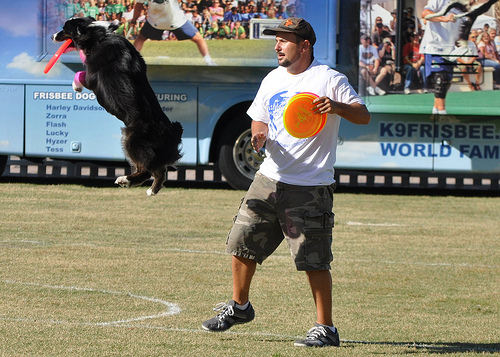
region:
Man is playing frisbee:
[194, 12, 369, 355]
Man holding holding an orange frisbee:
[198, 8, 379, 349]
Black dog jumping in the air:
[31, 11, 201, 208]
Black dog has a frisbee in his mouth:
[33, 10, 195, 215]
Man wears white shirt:
[198, 11, 366, 353]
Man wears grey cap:
[183, 7, 379, 353]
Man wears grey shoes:
[196, 10, 375, 355]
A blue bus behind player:
[7, 5, 499, 177]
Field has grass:
[3, 172, 498, 353]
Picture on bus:
[347, 1, 499, 116]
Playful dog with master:
[35, 10, 436, 350]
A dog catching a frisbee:
[13, 1, 215, 278]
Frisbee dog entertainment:
[19, 2, 405, 349]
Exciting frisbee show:
[8, 5, 498, 353]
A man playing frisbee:
[188, 9, 409, 347]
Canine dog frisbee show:
[17, 8, 451, 346]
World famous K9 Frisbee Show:
[6, 6, 498, 249]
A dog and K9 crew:
[15, 7, 412, 343]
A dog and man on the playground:
[23, 5, 497, 345]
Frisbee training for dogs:
[19, 7, 403, 347]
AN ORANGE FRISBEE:
[274, 88, 336, 141]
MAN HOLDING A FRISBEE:
[201, 13, 368, 353]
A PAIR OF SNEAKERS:
[196, 296, 350, 351]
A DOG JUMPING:
[34, 11, 199, 198]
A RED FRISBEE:
[41, 33, 78, 78]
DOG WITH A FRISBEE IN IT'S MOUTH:
[34, 12, 207, 203]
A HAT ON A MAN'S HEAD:
[259, 15, 336, 75]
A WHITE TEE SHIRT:
[224, 63, 364, 191]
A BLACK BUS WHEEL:
[206, 103, 306, 195]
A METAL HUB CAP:
[227, 113, 287, 183]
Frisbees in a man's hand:
[284, 87, 335, 141]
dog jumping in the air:
[46, 17, 183, 198]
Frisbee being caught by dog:
[37, 15, 77, 73]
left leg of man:
[281, 177, 341, 347]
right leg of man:
[201, 167, 281, 327]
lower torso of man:
[202, 162, 345, 349]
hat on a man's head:
[260, 16, 318, 43]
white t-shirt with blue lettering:
[236, 56, 371, 182]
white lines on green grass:
[11, 217, 498, 354]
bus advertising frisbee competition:
[2, 1, 498, 186]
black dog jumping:
[56, 17, 186, 194]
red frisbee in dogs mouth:
[43, 35, 72, 76]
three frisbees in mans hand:
[280, 89, 330, 141]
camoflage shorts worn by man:
[236, 170, 342, 275]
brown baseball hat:
[267, 12, 322, 43]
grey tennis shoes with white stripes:
[200, 298, 348, 345]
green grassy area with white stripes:
[15, 198, 202, 349]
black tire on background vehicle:
[213, 108, 266, 188]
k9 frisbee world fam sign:
[375, 115, 498, 172]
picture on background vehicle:
[141, 2, 266, 65]